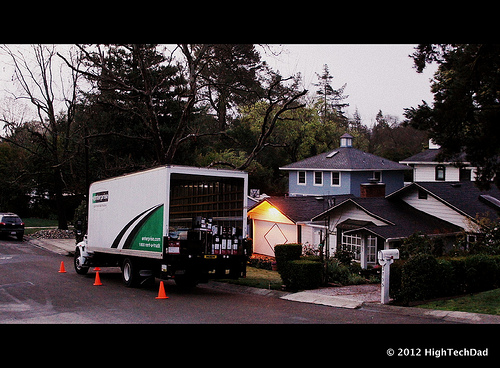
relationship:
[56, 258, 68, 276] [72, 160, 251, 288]
cone by truck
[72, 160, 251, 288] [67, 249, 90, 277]
truck has tire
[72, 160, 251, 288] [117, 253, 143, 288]
truck has tire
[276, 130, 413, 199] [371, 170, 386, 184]
house has window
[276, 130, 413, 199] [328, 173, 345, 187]
house has window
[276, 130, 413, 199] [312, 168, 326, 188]
house has window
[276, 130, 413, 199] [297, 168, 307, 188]
house has window